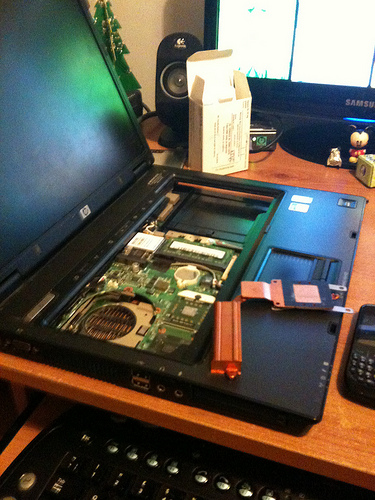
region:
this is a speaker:
[147, 21, 208, 144]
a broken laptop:
[2, 0, 354, 435]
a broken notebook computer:
[1, 3, 369, 427]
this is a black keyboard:
[0, 429, 353, 498]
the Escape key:
[66, 426, 106, 449]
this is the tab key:
[48, 475, 75, 493]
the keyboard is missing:
[66, 146, 265, 350]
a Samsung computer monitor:
[199, 2, 374, 133]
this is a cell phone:
[329, 301, 373, 401]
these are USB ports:
[126, 365, 153, 390]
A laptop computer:
[5, 35, 349, 436]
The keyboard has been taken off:
[54, 161, 297, 359]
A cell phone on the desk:
[343, 293, 374, 389]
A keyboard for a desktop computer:
[8, 416, 329, 498]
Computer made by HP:
[75, 196, 104, 227]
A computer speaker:
[147, 16, 202, 144]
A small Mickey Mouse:
[342, 117, 369, 159]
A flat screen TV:
[203, 3, 369, 131]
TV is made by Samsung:
[338, 91, 374, 113]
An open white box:
[184, 49, 259, 180]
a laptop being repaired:
[9, 93, 313, 372]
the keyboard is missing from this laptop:
[94, 172, 250, 356]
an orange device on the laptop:
[210, 271, 353, 399]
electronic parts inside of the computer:
[58, 242, 228, 350]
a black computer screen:
[17, 43, 188, 248]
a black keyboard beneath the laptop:
[17, 430, 211, 499]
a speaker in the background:
[144, 25, 208, 163]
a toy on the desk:
[331, 117, 371, 165]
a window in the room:
[224, 9, 369, 91]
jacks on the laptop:
[115, 364, 191, 405]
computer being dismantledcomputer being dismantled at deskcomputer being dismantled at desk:
[56, 172, 288, 248]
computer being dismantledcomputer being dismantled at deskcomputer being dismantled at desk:
[154, 138, 319, 401]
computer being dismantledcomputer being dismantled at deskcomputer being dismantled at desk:
[100, 130, 273, 423]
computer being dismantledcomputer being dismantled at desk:
[60, 137, 232, 428]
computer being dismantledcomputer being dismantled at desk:
[45, 150, 270, 435]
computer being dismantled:
[78, 170, 292, 380]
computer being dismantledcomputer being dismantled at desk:
[62, 145, 338, 430]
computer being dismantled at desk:
[77, 146, 350, 416]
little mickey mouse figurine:
[343, 121, 374, 166]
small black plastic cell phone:
[327, 298, 373, 414]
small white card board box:
[180, 40, 256, 180]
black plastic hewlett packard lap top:
[0, 1, 374, 441]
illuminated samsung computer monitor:
[196, 1, 372, 177]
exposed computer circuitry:
[47, 216, 247, 367]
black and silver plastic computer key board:
[0, 400, 374, 496]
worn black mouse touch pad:
[246, 243, 348, 321]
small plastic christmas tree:
[87, 0, 143, 100]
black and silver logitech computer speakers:
[151, 26, 206, 152]